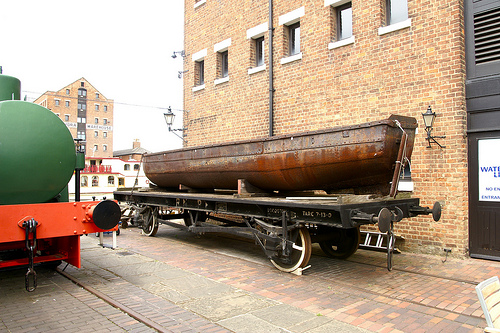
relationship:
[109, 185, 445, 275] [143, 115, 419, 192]
carrier holding boat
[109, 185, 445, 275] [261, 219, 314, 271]
carrier has left wheel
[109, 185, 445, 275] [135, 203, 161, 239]
carrier has back wheel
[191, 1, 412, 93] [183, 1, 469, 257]
windows on building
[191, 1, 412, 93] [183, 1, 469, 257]
windows are on building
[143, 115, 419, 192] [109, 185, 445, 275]
boat on carrier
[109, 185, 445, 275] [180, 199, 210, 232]
carrier has right wheel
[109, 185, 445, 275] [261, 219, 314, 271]
carrier has front wheel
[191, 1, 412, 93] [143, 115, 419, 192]
windows above boat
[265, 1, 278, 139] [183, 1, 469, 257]
pole on building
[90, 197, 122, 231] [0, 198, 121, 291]
circle on trailer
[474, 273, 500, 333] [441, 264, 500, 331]
chair in corner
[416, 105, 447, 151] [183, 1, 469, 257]
lamp on building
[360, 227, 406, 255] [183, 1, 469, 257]
ladder against building